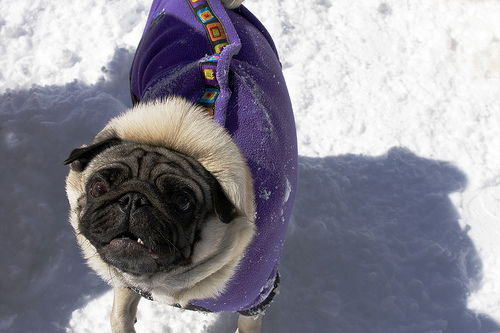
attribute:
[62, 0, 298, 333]
pug dog — standing, beige, looking up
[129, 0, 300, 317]
vest — purple, fleece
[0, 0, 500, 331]
snow — white, well trampled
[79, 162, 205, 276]
face — black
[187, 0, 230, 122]
stripe — colored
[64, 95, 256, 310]
fur — white